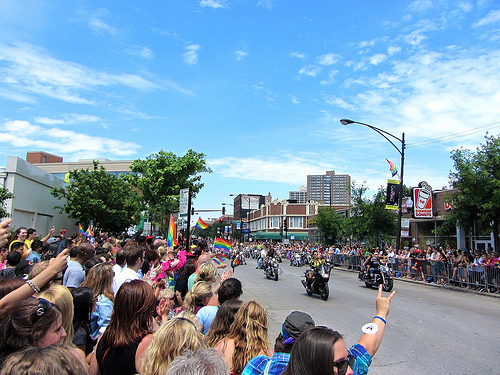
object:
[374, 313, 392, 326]
bracelet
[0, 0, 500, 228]
sky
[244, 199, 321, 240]
building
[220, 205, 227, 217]
light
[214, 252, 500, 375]
street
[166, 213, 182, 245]
flag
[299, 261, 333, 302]
bike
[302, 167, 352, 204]
building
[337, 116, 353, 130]
light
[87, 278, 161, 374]
people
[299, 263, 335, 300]
motorcycle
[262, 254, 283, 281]
motorcycle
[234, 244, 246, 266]
motorcycle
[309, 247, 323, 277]
person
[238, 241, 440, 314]
parade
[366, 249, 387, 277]
person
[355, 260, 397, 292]
motorbike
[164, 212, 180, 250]
flag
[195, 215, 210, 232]
flag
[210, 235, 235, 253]
flag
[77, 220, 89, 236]
flag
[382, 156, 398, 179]
flag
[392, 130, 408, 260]
pole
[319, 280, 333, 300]
tire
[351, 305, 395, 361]
arm